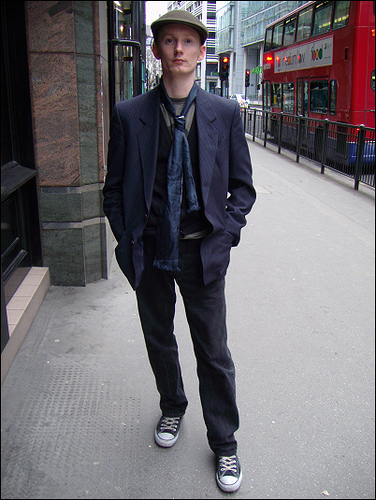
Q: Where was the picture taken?
A: A city.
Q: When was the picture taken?
A: Daytime.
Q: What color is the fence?
A: Black.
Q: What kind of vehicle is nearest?
A: A bus.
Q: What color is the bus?
A: Red.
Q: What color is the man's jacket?
A: Blue.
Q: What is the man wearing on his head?
A: A hat.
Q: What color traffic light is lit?
A: Red.